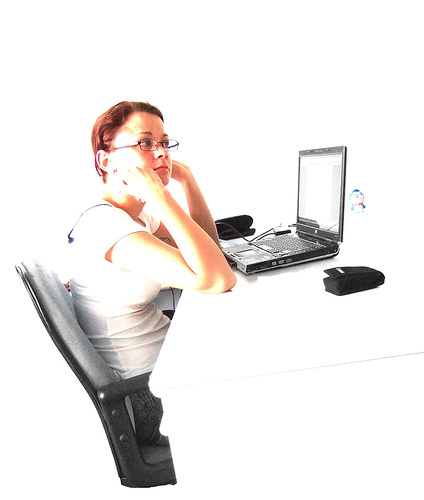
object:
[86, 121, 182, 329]
girl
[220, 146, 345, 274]
computer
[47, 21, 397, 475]
office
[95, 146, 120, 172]
ear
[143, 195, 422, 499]
desk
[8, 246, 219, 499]
chair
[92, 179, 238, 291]
arm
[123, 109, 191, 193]
face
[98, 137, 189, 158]
glasses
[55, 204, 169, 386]
shirt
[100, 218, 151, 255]
sleeve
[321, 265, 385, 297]
case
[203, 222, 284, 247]
wires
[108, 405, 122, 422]
bolt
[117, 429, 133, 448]
bolt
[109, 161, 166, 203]
hand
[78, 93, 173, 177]
hair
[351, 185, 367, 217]
penguin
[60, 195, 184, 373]
blouse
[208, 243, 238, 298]
elbows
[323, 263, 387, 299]
cell phone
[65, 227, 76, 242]
ear buds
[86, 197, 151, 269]
shoulder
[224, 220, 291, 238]
cords